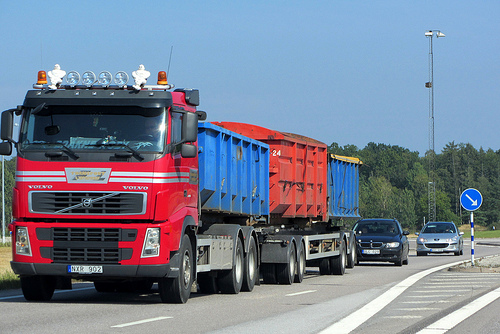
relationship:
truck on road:
[2, 62, 367, 303] [2, 239, 498, 332]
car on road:
[352, 216, 411, 264] [2, 239, 498, 332]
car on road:
[414, 219, 462, 256] [2, 239, 498, 332]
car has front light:
[352, 216, 411, 264] [384, 242, 401, 250]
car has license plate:
[352, 216, 411, 264] [362, 249, 379, 254]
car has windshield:
[352, 216, 411, 264] [359, 220, 399, 236]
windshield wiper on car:
[373, 230, 400, 235] [352, 216, 411, 264]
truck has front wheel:
[2, 62, 367, 303] [160, 228, 197, 307]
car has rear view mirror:
[352, 216, 411, 264] [403, 228, 411, 237]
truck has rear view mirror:
[2, 62, 367, 303] [172, 111, 198, 151]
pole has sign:
[456, 187, 483, 265] [458, 188, 485, 211]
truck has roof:
[2, 62, 367, 303] [23, 66, 366, 165]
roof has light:
[23, 66, 366, 165] [157, 71, 168, 86]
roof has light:
[23, 66, 366, 165] [36, 69, 49, 86]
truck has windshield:
[2, 62, 367, 303] [19, 104, 167, 157]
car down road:
[352, 216, 411, 264] [2, 239, 498, 332]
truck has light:
[2, 62, 367, 303] [157, 71, 168, 86]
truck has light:
[2, 62, 367, 303] [36, 69, 49, 86]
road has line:
[2, 239, 498, 332] [309, 253, 490, 333]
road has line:
[2, 239, 498, 332] [408, 284, 500, 333]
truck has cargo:
[2, 62, 367, 303] [195, 123, 272, 222]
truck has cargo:
[2, 62, 367, 303] [327, 154, 365, 219]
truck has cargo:
[2, 62, 367, 303] [211, 121, 330, 221]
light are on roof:
[157, 71, 168, 86] [23, 66, 366, 165]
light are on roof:
[36, 69, 49, 86] [23, 66, 366, 165]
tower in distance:
[424, 30, 446, 222] [346, 8, 499, 230]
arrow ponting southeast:
[465, 192, 478, 208] [472, 202, 498, 255]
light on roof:
[157, 71, 168, 86] [23, 66, 366, 165]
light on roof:
[36, 69, 49, 86] [23, 66, 366, 165]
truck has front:
[2, 62, 367, 303] [14, 91, 167, 267]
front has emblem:
[14, 91, 167, 267] [64, 168, 110, 186]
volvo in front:
[119, 181, 151, 193] [14, 91, 167, 267]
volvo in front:
[28, 183, 57, 190] [14, 91, 167, 267]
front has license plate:
[14, 91, 167, 267] [68, 263, 107, 274]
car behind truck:
[352, 216, 411, 264] [2, 62, 367, 303]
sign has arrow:
[458, 188, 485, 211] [465, 192, 478, 208]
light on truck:
[157, 71, 168, 86] [2, 62, 367, 303]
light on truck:
[36, 69, 49, 86] [2, 62, 367, 303]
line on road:
[309, 253, 490, 333] [2, 239, 498, 332]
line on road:
[408, 284, 500, 333] [2, 239, 498, 332]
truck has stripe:
[2, 62, 367, 303] [14, 169, 194, 179]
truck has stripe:
[2, 62, 367, 303] [15, 175, 202, 185]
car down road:
[414, 219, 462, 256] [2, 239, 498, 332]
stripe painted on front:
[14, 169, 194, 179] [14, 91, 167, 267]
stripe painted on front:
[15, 175, 202, 185] [14, 91, 167, 267]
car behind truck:
[414, 219, 462, 256] [2, 62, 367, 303]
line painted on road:
[309, 253, 490, 333] [2, 239, 498, 332]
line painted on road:
[408, 284, 500, 333] [2, 239, 498, 332]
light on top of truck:
[157, 71, 168, 86] [2, 62, 367, 303]